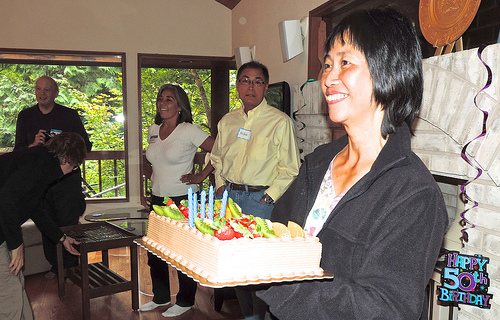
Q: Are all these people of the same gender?
A: No, they are both male and female.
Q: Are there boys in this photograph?
A: No, there are no boys.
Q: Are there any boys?
A: No, there are no boys.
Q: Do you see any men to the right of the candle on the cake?
A: Yes, there is a man to the right of the candle.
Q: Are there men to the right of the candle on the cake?
A: Yes, there is a man to the right of the candle.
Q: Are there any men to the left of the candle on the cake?
A: No, the man is to the right of the candle.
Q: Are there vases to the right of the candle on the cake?
A: No, there is a man to the right of the candle.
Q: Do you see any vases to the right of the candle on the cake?
A: No, there is a man to the right of the candle.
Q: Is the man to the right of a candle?
A: Yes, the man is to the right of a candle.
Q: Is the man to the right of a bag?
A: No, the man is to the right of a candle.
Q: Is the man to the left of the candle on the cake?
A: No, the man is to the right of the candle.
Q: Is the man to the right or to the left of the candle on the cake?
A: The man is to the right of the candle.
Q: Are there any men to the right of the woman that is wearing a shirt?
A: Yes, there is a man to the right of the woman.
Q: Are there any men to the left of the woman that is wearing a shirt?
A: No, the man is to the right of the woman.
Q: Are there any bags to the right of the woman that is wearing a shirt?
A: No, there is a man to the right of the woman.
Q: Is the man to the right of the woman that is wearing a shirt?
A: Yes, the man is to the right of the woman.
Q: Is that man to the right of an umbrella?
A: No, the man is to the right of the woman.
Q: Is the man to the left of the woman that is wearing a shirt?
A: No, the man is to the right of the woman.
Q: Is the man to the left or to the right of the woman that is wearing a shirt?
A: The man is to the right of the woman.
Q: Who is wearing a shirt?
A: The man is wearing a shirt.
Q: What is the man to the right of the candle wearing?
A: The man is wearing a shirt.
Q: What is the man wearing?
A: The man is wearing a shirt.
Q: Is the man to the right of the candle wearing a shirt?
A: Yes, the man is wearing a shirt.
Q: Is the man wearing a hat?
A: No, the man is wearing a shirt.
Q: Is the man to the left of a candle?
A: No, the man is to the right of a candle.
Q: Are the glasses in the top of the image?
A: Yes, the glasses are in the top of the image.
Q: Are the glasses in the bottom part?
A: No, the glasses are in the top of the image.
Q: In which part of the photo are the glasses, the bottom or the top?
A: The glasses are in the top of the image.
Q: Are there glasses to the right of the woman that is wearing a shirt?
A: Yes, there are glasses to the right of the woman.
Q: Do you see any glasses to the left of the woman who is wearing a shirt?
A: No, the glasses are to the right of the woman.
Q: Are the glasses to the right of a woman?
A: Yes, the glasses are to the right of a woman.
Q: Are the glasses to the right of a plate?
A: No, the glasses are to the right of a woman.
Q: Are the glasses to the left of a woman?
A: No, the glasses are to the right of a woman.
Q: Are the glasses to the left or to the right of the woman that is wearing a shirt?
A: The glasses are to the right of the woman.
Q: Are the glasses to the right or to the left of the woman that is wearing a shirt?
A: The glasses are to the right of the woman.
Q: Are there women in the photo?
A: Yes, there is a woman.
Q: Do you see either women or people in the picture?
A: Yes, there is a woman.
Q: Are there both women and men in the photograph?
A: Yes, there are both a woman and a man.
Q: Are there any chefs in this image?
A: No, there are no chefs.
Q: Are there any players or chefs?
A: No, there are no chefs or players.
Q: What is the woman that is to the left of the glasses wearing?
A: The woman is wearing a shirt.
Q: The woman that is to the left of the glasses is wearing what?
A: The woman is wearing a shirt.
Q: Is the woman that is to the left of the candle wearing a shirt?
A: Yes, the woman is wearing a shirt.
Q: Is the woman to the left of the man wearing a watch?
A: No, the woman is wearing a shirt.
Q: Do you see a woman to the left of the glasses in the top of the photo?
A: Yes, there is a woman to the left of the glasses.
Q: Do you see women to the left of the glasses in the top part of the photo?
A: Yes, there is a woman to the left of the glasses.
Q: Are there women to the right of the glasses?
A: No, the woman is to the left of the glasses.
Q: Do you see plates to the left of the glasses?
A: No, there is a woman to the left of the glasses.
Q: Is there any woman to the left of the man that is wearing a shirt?
A: Yes, there is a woman to the left of the man.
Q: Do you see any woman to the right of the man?
A: No, the woman is to the left of the man.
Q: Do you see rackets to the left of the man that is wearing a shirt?
A: No, there is a woman to the left of the man.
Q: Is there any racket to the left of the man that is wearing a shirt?
A: No, there is a woman to the left of the man.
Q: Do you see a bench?
A: No, there are no benches.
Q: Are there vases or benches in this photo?
A: No, there are no benches or vases.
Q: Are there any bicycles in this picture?
A: No, there are no bicycles.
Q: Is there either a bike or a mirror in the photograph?
A: No, there are no bikes or mirrors.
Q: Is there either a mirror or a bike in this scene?
A: No, there are no bikes or mirrors.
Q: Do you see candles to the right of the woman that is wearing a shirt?
A: Yes, there is a candle to the right of the woman.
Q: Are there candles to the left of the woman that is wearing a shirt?
A: No, the candle is to the right of the woman.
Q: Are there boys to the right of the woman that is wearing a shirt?
A: No, there is a candle to the right of the woman.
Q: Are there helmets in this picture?
A: No, there are no helmets.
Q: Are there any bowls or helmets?
A: No, there are no helmets or bowls.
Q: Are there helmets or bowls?
A: No, there are no helmets or bowls.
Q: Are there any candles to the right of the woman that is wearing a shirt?
A: Yes, there is a candle to the right of the woman.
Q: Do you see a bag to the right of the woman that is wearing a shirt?
A: No, there is a candle to the right of the woman.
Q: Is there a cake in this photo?
A: Yes, there is a cake.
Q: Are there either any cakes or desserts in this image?
A: Yes, there is a cake.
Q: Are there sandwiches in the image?
A: No, there are no sandwiches.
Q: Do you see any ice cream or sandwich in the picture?
A: No, there are no sandwiches or ice cream.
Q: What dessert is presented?
A: The dessert is a cake.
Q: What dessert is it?
A: The dessert is a cake.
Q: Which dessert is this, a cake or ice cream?
A: That is a cake.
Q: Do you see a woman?
A: Yes, there is a woman.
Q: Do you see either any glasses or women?
A: Yes, there is a woman.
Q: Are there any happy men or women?
A: Yes, there is a happy woman.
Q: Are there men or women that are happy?
A: Yes, the woman is happy.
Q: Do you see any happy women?
A: Yes, there is a happy woman.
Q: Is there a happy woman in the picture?
A: Yes, there is a happy woman.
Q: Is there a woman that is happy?
A: Yes, there is a woman that is happy.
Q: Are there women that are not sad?
A: Yes, there is a happy woman.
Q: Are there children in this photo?
A: No, there are no children.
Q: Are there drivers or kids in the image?
A: No, there are no kids or drivers.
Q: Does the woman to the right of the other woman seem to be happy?
A: Yes, the woman is happy.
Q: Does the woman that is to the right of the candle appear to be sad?
A: No, the woman is happy.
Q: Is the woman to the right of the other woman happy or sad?
A: The woman is happy.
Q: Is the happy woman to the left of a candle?
A: No, the woman is to the right of a candle.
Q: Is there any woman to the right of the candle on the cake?
A: Yes, there is a woman to the right of the candle.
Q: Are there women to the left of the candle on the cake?
A: No, the woman is to the right of the candle.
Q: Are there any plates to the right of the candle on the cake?
A: No, there is a woman to the right of the candle.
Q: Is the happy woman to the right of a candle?
A: Yes, the woman is to the right of a candle.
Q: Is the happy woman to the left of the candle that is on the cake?
A: No, the woman is to the right of the candle.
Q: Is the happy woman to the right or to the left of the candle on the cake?
A: The woman is to the right of the candle.